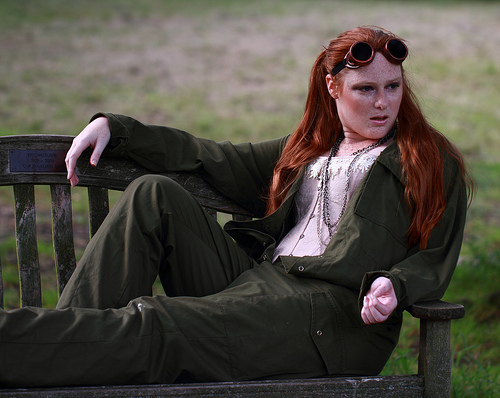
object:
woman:
[2, 24, 469, 390]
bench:
[2, 131, 468, 396]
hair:
[387, 122, 472, 251]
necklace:
[321, 125, 378, 236]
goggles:
[349, 37, 409, 65]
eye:
[382, 82, 401, 92]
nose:
[372, 88, 390, 111]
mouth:
[368, 112, 391, 126]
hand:
[61, 115, 111, 187]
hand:
[359, 275, 398, 325]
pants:
[1, 173, 403, 387]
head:
[324, 25, 409, 142]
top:
[271, 153, 381, 268]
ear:
[324, 72, 339, 100]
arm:
[396, 206, 483, 276]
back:
[1, 134, 265, 316]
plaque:
[7, 144, 64, 176]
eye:
[352, 84, 376, 95]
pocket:
[227, 289, 347, 379]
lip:
[370, 113, 391, 119]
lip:
[370, 118, 389, 125]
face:
[334, 53, 404, 140]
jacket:
[89, 112, 467, 379]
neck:
[342, 126, 360, 145]